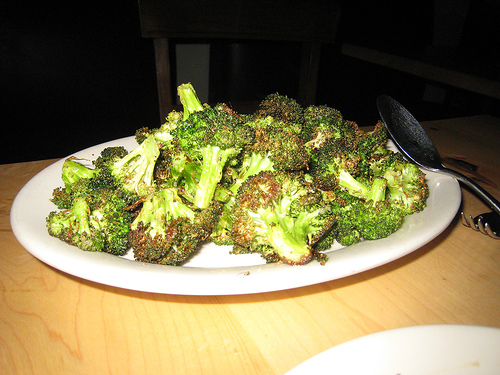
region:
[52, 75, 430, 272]
The broccoli is green.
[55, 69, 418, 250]
Broccoli on a plate.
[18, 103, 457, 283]
The plate is white.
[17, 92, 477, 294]
The plate is round.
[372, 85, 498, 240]
The utensils are silver.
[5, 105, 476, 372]
The plate is on a table.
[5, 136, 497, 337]
The table is wooden.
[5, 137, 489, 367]
the table is tan.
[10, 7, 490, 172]
Background is black.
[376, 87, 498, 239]
Utensils are a spoon and fork.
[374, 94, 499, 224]
a gray metal spoon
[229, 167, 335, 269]
a piece of green broccoli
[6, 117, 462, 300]
a white plate on the table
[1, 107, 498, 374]
a brown wooden table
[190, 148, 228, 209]
the green stem of broccoli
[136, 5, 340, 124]
a wooden chair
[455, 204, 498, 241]
the tines of a fork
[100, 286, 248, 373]
grains in the wood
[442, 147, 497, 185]
a knot in the wood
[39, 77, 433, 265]
a pile of broccoli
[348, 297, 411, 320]
Table made out of wood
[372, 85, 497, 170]
Silver spoon on white plate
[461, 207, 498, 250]
Silver fork on wooden table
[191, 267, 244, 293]
Small edge of white plate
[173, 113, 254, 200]
One piece of green broccoli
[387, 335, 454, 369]
Another plate on wooden table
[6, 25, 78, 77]
Pitch black background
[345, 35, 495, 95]
Table in the background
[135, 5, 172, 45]
Brown table behind wooden table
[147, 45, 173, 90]
Small part of the legs of the brown table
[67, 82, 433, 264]
a plate of broccoli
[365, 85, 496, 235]
a spoon and a fork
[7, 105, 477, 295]
broccoli sits on a white plate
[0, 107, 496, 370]
a tan-colored table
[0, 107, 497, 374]
a plate of broccoli sits on a wooden table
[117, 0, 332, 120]
a dark brown chair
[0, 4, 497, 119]
lights are off in this room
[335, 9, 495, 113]
another wooden table in the background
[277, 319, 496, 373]
another white plate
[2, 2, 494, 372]
A white plate sitting on a table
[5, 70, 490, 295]
A white plate filled with broccoli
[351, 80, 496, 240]
A spoon resting on a plate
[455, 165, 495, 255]
A fork laying on a table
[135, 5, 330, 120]
A wooden chair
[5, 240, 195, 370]
A wooden table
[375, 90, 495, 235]
A spoon beside a fork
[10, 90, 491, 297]
A plate of broccoli beside a fork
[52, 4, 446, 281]
A chair behind a plate of broccoli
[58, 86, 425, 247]
Cooked broccoli